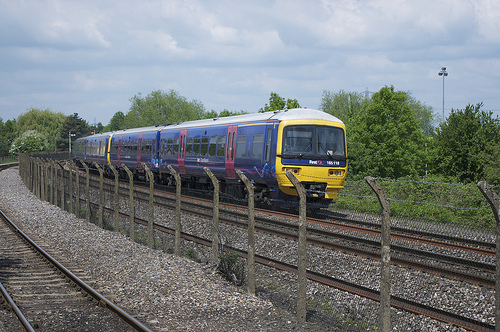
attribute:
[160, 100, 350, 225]
car — yellow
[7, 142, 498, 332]
fencing — chain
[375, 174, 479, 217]
barbwire — overhang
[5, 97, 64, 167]
trees — green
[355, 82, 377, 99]
frame — large, electrical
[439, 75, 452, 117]
pole — electrical, light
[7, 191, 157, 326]
tracks — laid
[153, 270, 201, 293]
stones — gravel, lining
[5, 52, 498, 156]
skies — lightly, cloudy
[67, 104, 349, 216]
train — yellow, passenger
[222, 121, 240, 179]
doors — access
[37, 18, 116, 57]
clouds — white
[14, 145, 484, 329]
line — fence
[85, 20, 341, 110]
sky — white, blue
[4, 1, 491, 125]
sky — cloudy, white and blue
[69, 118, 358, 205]
train — yellow